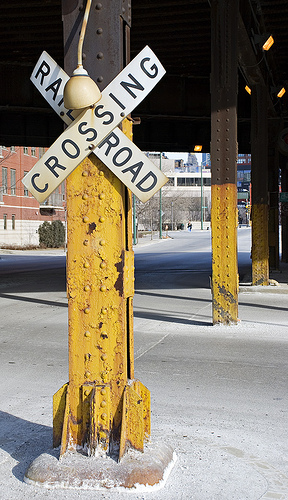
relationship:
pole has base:
[47, 0, 153, 463] [26, 439, 174, 490]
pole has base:
[249, 87, 276, 288] [238, 275, 287, 296]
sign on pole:
[21, 46, 170, 204] [47, 0, 153, 463]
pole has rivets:
[47, 0, 153, 463] [84, 238, 91, 249]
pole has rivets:
[47, 0, 153, 463] [98, 192, 106, 203]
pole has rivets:
[47, 0, 153, 463] [99, 284, 108, 294]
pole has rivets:
[47, 0, 153, 463] [98, 51, 105, 60]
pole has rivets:
[47, 0, 153, 463] [84, 329, 93, 341]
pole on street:
[47, 0, 153, 463] [0, 228, 287, 500]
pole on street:
[207, 1, 242, 327] [0, 228, 287, 500]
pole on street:
[249, 87, 276, 288] [0, 228, 287, 500]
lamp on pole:
[259, 35, 277, 51] [228, 2, 275, 90]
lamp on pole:
[276, 85, 286, 102] [228, 2, 275, 90]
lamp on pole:
[242, 83, 251, 97] [228, 2, 275, 90]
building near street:
[0, 148, 67, 258] [0, 228, 287, 500]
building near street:
[134, 149, 218, 235] [0, 228, 287, 500]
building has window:
[0, 148, 67, 258] [10, 168, 19, 196]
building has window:
[0, 148, 67, 258] [0, 166, 10, 203]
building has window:
[0, 148, 67, 258] [9, 213, 18, 233]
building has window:
[0, 148, 67, 258] [22, 147, 33, 159]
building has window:
[134, 149, 218, 235] [177, 176, 185, 187]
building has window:
[134, 149, 218, 235] [187, 177, 197, 187]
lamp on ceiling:
[259, 35, 277, 51] [1, 1, 286, 154]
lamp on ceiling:
[242, 83, 251, 97] [1, 1, 286, 154]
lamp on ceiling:
[276, 85, 286, 102] [1, 1, 286, 154]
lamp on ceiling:
[190, 144, 203, 154] [1, 1, 286, 154]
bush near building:
[38, 222, 54, 251] [0, 148, 67, 258]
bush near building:
[51, 219, 67, 249] [0, 148, 67, 258]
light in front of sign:
[62, 1, 100, 110] [21, 46, 170, 204]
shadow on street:
[2, 409, 60, 484] [0, 228, 287, 500]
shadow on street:
[1, 294, 67, 315] [0, 228, 287, 500]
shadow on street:
[134, 308, 213, 335] [0, 228, 287, 500]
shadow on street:
[135, 288, 214, 308] [0, 228, 287, 500]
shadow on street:
[238, 301, 287, 317] [0, 228, 287, 500]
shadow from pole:
[2, 409, 60, 484] [47, 0, 153, 463]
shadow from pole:
[134, 308, 213, 335] [207, 1, 242, 327]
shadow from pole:
[1, 294, 67, 315] [207, 1, 242, 327]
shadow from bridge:
[1, 251, 253, 294] [1, 1, 286, 154]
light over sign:
[62, 1, 100, 110] [21, 46, 170, 204]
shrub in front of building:
[38, 222, 54, 251] [0, 148, 67, 258]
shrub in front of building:
[51, 219, 67, 249] [0, 148, 67, 258]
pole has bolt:
[47, 0, 153, 463] [83, 167, 89, 180]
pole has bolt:
[47, 0, 153, 463] [81, 194, 90, 203]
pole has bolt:
[207, 1, 242, 327] [225, 194, 230, 202]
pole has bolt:
[207, 1, 242, 327] [227, 127, 231, 136]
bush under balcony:
[38, 222, 54, 251] [38, 193, 66, 215]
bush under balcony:
[51, 219, 67, 249] [38, 193, 66, 215]